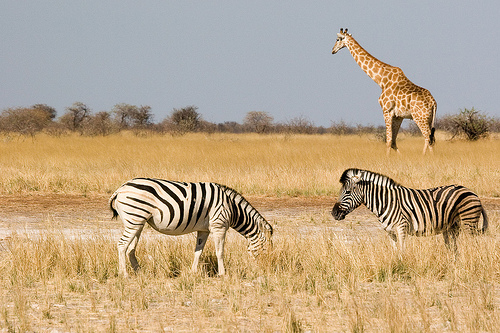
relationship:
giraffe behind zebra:
[332, 27, 438, 158] [331, 167, 489, 250]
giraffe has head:
[332, 27, 438, 158] [333, 28, 350, 55]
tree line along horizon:
[0, 101, 499, 136] [0, 128, 500, 134]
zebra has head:
[331, 167, 489, 250] [332, 168, 367, 221]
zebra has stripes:
[331, 167, 489, 250] [402, 189, 436, 233]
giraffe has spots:
[332, 27, 438, 158] [391, 87, 408, 104]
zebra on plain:
[331, 167, 489, 250] [0, 132, 499, 333]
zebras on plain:
[109, 177, 274, 278] [0, 132, 499, 333]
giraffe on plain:
[332, 27, 438, 158] [0, 132, 499, 333]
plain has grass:
[0, 132, 499, 333] [0, 135, 382, 168]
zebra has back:
[331, 167, 489, 250] [401, 185, 439, 198]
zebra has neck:
[331, 167, 489, 250] [366, 175, 394, 217]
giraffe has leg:
[332, 27, 438, 158] [379, 92, 395, 153]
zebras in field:
[109, 177, 274, 278] [11, 129, 464, 331]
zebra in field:
[328, 156, 484, 251] [11, 129, 464, 331]